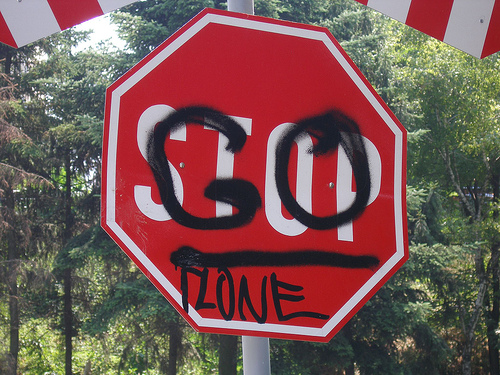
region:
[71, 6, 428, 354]
a stop sign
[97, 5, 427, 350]
a stop sign painted over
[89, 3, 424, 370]
a stop sign painted over on a post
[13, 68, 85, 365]
trees behind the sign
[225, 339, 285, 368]
a post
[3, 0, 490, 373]
this is a sign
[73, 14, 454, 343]
the sign is red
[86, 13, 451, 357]
the sign has white trim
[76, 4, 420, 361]
red trim on sign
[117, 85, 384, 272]
stop on the sign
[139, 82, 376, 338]
graffiti on the sign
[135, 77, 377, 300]
the graffiti is black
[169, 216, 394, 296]
black line on sign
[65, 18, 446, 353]
sign is octagon shape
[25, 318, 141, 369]
sunlight on the trees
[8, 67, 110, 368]
the trees are tall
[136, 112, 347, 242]
the letters are white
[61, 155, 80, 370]
the bark is on the tree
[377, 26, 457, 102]
the leaves are golden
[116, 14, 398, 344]
the sign is red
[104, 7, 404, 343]
Stop sign on a pole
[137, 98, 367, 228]
Spray painted word on stop sign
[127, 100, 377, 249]
White word STOP on sign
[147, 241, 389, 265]
Black painted line on a sign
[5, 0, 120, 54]
Red and white warning sign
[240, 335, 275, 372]
White pole with sign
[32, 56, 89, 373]
Tall tree behind a sign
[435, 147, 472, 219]
Branch on a tree behind a sign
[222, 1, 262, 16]
White pole with a sign on it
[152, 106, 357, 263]
Black painted writing on the sign.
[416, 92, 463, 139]
The tree has leaves.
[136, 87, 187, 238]
A letter on a sign.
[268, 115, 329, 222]
A letter on a sign.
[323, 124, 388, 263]
A letter on a sign.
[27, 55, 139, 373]
A tree in the woods.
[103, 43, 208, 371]
A tree in the woods.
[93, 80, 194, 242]
A letter on a sign.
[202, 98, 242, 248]
A letter on a sign.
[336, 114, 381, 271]
A letter on a sign.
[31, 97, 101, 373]
A tree in the woods.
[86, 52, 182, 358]
A tree in the woods.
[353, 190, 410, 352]
A tree in the woods.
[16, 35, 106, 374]
A tree in the woods.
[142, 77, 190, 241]
A letter on a sign.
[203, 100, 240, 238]
A letter on a sign.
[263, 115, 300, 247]
A letter on a sign.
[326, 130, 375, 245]
A letter on a sign.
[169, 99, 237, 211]
A letter on a sign.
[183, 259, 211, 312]
A letter on a sign.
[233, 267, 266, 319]
A letter on a sign.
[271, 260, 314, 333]
A letter on a sign.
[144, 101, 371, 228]
the word go in black paint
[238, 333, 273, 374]
a light gray colored sign pole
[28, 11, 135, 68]
the white colored sky through the trees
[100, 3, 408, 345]
the sign is an ocotagon in shape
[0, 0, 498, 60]
red and white striped traffic control arms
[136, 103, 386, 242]
the white word stop under the black graffiti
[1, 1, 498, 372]
tall skinny green trees